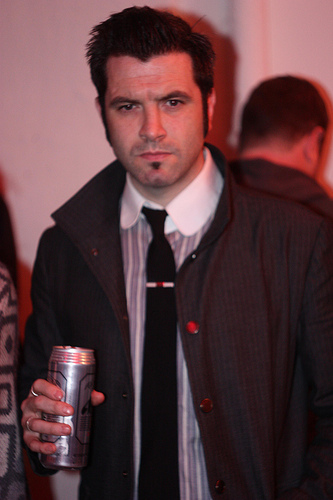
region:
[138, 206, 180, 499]
black cotton neck tie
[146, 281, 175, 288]
white and red tie tack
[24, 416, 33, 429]
silver ring on finger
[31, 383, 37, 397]
ring on mans hand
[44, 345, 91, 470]
silver can in hand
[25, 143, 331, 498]
grey striped dress jacket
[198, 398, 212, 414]
red button on jacket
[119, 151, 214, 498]
button down dress shirt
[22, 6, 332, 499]
man wearing two rings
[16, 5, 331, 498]
man holding silver can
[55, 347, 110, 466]
the can is silver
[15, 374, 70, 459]
the hand has two rings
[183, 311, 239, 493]
the buttons are three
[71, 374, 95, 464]
wriiing is on the can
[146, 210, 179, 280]
the tie is black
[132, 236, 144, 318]
the shirt is striped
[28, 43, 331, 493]
the guy is drinking beer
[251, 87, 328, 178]
the guy is facing the other side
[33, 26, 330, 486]
the guy is facing the camera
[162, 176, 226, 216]
the colar is white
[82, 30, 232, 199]
man looking at the camera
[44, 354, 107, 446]
drink in man's hand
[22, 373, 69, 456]
fingers of the man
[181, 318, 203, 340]
button on the jacket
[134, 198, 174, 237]
knot on the tie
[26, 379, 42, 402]
ring on man's finger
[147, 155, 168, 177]
hair on the man's chin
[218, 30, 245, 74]
shadow behind the man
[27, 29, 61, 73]
wall in the background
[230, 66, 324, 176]
head of the person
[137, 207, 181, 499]
man wearing a plain ling black necktie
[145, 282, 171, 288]
tie tack on necktie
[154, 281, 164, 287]
red detail on tie tack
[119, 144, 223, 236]
white collar on shirt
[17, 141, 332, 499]
man wearing a dark jacket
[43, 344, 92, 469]
silver aluminum can in hand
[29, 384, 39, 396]
silver ring on index finger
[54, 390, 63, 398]
fingernail on finger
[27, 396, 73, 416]
finger next to finger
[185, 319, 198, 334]
red button on jacket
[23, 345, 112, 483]
man is holding can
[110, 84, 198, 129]
man is staring at the camera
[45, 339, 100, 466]
can is in the man's hand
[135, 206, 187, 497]
man is wearing a tie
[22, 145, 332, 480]
man is wearing jacket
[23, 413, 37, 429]
man has ring on finger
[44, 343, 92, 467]
can is silver in color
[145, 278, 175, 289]
man has a tie clip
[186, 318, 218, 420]
buttons are on the jacket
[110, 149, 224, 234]
man has a white collar